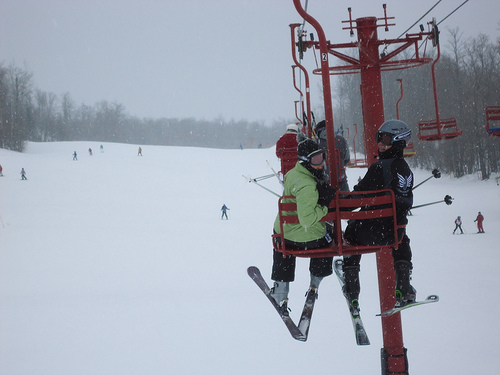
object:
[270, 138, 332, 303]
people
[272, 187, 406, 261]
lift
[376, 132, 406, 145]
goggles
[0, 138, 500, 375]
snow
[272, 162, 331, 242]
jacket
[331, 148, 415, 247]
jacket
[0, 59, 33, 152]
trees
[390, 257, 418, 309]
boots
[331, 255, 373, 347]
skis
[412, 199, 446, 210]
poles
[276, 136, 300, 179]
suit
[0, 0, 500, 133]
sky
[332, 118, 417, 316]
man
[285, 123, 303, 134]
hat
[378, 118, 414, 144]
helmet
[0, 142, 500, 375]
ground